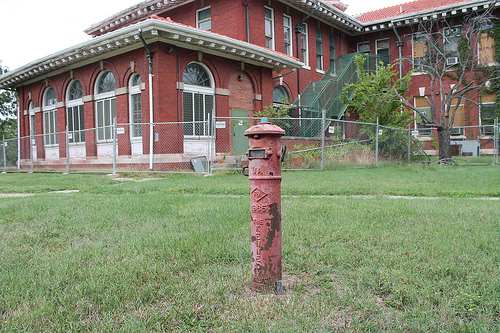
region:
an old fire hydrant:
[235, 109, 300, 301]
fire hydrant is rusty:
[241, 115, 296, 298]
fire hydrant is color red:
[237, 110, 295, 300]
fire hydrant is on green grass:
[205, 100, 325, 310]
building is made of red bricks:
[2, 5, 497, 163]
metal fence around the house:
[2, 108, 497, 184]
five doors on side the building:
[15, 62, 157, 173]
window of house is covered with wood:
[471, 27, 497, 67]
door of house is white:
[178, 60, 220, 164]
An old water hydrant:
[232, 110, 304, 302]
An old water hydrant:
[230, 111, 303, 308]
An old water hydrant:
[227, 117, 295, 299]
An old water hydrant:
[228, 119, 305, 301]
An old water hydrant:
[236, 117, 301, 299]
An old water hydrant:
[235, 120, 295, 301]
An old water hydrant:
[235, 121, 300, 307]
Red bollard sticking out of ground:
[231, 103, 303, 304]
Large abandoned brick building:
[30, 0, 482, 179]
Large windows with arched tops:
[14, 62, 221, 172]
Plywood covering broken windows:
[426, 77, 476, 154]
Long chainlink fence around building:
[1, 120, 496, 174]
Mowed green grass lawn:
[10, 151, 496, 331]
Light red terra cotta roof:
[349, 2, 444, 27]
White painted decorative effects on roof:
[5, 40, 307, 79]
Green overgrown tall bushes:
[339, 44, 421, 169]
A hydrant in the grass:
[240, 115, 287, 291]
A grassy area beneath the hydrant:
[0, 162, 495, 332]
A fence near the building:
[0, 113, 494, 172]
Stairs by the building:
[286, 53, 385, 136]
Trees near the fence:
[347, 13, 499, 164]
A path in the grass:
[1, 191, 498, 198]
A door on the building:
[229, 108, 249, 153]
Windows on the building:
[263, 7, 336, 71]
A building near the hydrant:
[0, 1, 498, 167]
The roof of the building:
[356, 0, 456, 25]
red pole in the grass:
[242, 118, 287, 295]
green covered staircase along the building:
[289, 50, 356, 137]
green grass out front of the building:
[0, 156, 499, 331]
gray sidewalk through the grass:
[0, 188, 499, 202]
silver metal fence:
[1, 112, 499, 173]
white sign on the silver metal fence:
[212, 118, 227, 128]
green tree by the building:
[337, 53, 431, 162]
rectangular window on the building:
[259, 4, 278, 49]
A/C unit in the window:
[443, 52, 459, 67]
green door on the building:
[228, 103, 253, 155]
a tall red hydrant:
[243, 121, 285, 289]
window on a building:
[59, 78, 86, 148]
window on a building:
[34, 90, 64, 146]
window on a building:
[178, 62, 213, 136]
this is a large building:
[28, 13, 345, 208]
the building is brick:
[72, 28, 213, 125]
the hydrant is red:
[233, 120, 335, 295]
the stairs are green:
[259, 41, 460, 176]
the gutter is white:
[154, 26, 306, 81]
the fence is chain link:
[87, 99, 253, 192]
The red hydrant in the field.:
[236, 114, 288, 296]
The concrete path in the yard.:
[0, 173, 165, 197]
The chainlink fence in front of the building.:
[0, 117, 495, 176]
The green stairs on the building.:
[280, 51, 387, 138]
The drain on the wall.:
[137, 28, 153, 172]